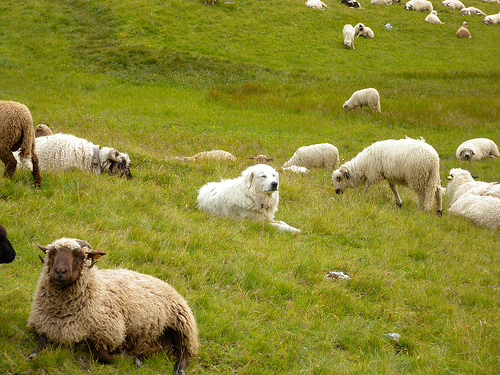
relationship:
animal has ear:
[330, 133, 442, 215] [330, 165, 349, 183]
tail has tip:
[13, 104, 33, 173] [17, 153, 34, 170]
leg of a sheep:
[173, 323, 198, 375] [113, 272, 172, 373]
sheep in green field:
[12, 129, 133, 180] [2, 100, 192, 175]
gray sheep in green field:
[287, 130, 344, 190] [16, 164, 443, 330]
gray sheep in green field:
[341, 87, 381, 116] [123, 102, 439, 320]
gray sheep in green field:
[341, 100, 367, 120] [133, 50, 476, 145]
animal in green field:
[330, 133, 442, 215] [202, 283, 324, 367]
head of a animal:
[35, 233, 101, 301] [24, 235, 200, 374]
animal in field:
[452, 16, 475, 50] [419, 2, 499, 78]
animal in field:
[330, 133, 442, 215] [326, 118, 498, 308]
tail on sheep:
[13, 102, 33, 163] [1, 99, 55, 189]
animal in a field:
[194, 160, 309, 231] [56, 23, 308, 119]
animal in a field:
[24, 239, 207, 369] [71, 23, 318, 111]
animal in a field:
[333, 138, 450, 216] [77, 45, 303, 124]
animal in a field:
[281, 142, 341, 174] [226, 240, 466, 363]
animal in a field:
[194, 162, 300, 231] [343, 82, 383, 112]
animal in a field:
[341, 20, 357, 45] [19, 5, 333, 115]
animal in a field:
[281, 132, 342, 176] [29, 13, 318, 128]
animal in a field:
[456, 19, 472, 38] [24, 19, 309, 117]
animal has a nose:
[194, 162, 300, 231] [269, 180, 279, 193]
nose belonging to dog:
[271, 180, 279, 188] [195, 162, 302, 235]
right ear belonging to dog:
[240, 165, 253, 190] [195, 162, 302, 235]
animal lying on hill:
[456, 19, 472, 38] [2, 1, 484, 128]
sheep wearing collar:
[12, 129, 133, 180] [91, 142, 102, 171]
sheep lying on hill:
[339, 0, 363, 10] [2, 1, 484, 108]